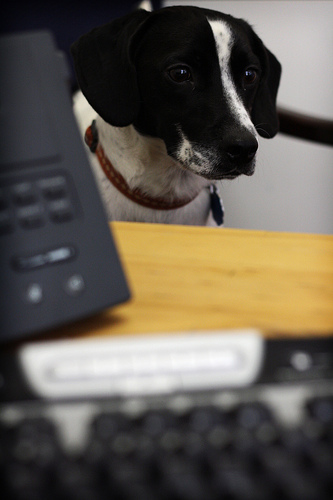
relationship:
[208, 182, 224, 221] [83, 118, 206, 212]
name tag on collar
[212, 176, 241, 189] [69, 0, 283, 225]
whiskers on dog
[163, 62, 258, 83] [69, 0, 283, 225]
eyes on dog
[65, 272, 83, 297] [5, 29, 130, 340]
button on front phone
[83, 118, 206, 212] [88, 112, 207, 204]
collar on neck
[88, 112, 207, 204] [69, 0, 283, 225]
neck of dog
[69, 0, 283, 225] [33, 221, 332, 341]
dog behind desk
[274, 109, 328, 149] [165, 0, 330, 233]
moulding on wall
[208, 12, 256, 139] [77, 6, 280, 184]
stripe on head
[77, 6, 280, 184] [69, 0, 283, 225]
head of dog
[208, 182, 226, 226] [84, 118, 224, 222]
name tag on dog's collar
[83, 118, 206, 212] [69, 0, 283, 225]
collar on dog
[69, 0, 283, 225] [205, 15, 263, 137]
dog has stripe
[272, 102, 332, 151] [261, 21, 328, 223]
baseboard on wall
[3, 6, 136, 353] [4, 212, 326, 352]
phone on desk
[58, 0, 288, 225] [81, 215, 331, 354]
dog by desk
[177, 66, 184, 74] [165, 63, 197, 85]
reflection on dog eye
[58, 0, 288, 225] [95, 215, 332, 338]
dog near desk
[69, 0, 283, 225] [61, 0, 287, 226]
dog has head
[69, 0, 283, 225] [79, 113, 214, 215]
dog has collar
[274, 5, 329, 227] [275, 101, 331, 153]
wall has baseboard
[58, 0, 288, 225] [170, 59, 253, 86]
dog has eyes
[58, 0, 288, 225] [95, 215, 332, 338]
dog looks desk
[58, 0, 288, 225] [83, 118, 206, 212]
dog has collar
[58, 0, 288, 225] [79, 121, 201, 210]
dog wears collar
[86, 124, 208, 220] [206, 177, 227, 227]
collar has tag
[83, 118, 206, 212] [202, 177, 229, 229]
collar has tag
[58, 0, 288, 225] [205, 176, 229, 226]
dog has tag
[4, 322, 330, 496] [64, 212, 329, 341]
keyboard on desk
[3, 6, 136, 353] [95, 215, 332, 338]
phone on desk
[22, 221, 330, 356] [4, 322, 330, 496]
desk on keyboard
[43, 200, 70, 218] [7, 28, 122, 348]
button on phone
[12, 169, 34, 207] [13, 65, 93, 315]
button on phone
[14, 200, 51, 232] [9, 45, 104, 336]
button on phone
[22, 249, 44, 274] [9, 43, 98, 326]
button on phone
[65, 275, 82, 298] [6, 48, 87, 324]
button on phone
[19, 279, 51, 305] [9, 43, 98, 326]
button on phone